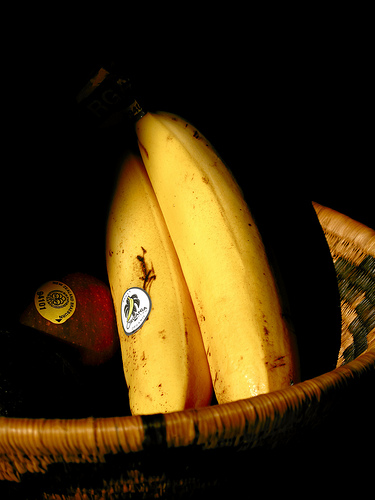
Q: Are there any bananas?
A: Yes, there is a banana.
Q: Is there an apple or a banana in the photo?
A: Yes, there is a banana.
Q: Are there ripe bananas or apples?
A: Yes, there is a ripe banana.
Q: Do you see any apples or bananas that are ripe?
A: Yes, the banana is ripe.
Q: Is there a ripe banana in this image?
A: Yes, there is a ripe banana.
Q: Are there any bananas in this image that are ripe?
A: Yes, there is a banana that is ripe.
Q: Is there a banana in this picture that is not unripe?
A: Yes, there is an ripe banana.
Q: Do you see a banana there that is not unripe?
A: Yes, there is an ripe banana.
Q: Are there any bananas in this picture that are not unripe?
A: Yes, there is an ripe banana.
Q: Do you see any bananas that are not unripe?
A: Yes, there is an ripe banana.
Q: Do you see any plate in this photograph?
A: No, there are no plates.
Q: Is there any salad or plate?
A: No, there are no plates or salad.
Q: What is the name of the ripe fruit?
A: The fruit is a banana.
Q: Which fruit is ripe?
A: The fruit is a banana.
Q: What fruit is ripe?
A: The fruit is a banana.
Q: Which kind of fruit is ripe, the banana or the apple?
A: The banana is ripe.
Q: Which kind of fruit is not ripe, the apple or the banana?
A: The apple is not ripe.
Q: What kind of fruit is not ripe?
A: The fruit is an apple.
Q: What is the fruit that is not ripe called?
A: The fruit is an apple.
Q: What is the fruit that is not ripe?
A: The fruit is an apple.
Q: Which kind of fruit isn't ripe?
A: The fruit is an apple.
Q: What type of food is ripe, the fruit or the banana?
A: The banana is ripe.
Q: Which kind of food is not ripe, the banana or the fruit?
A: The fruit is not ripe.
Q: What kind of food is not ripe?
A: The food is a fruit.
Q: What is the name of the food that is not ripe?
A: The food is a fruit.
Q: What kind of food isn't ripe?
A: The food is a fruit.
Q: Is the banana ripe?
A: Yes, the banana is ripe.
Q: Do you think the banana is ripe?
A: Yes, the banana is ripe.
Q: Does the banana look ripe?
A: Yes, the banana is ripe.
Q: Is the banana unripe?
A: No, the banana is ripe.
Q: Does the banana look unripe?
A: No, the banana is ripe.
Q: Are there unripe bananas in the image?
A: No, there is a banana but it is ripe.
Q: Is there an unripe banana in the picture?
A: No, there is a banana but it is ripe.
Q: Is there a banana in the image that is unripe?
A: No, there is a banana but it is ripe.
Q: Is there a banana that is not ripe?
A: No, there is a banana but it is ripe.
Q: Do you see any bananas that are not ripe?
A: No, there is a banana but it is ripe.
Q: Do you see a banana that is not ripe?
A: No, there is a banana but it is ripe.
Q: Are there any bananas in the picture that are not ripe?
A: No, there is a banana but it is ripe.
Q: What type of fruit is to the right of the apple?
A: The fruit is a banana.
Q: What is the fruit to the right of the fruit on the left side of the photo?
A: The fruit is a banana.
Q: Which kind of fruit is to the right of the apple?
A: The fruit is a banana.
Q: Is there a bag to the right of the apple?
A: No, there is a banana to the right of the apple.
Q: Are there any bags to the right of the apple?
A: No, there is a banana to the right of the apple.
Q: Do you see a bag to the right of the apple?
A: No, there is a banana to the right of the apple.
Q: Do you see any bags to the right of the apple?
A: No, there is a banana to the right of the apple.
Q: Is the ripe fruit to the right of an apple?
A: Yes, the banana is to the right of an apple.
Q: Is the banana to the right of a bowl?
A: No, the banana is to the right of an apple.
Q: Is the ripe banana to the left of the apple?
A: No, the banana is to the right of the apple.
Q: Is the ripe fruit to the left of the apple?
A: No, the banana is to the right of the apple.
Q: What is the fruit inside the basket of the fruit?
A: The fruit is a banana.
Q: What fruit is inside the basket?
A: The fruit is a banana.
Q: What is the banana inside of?
A: The banana is inside the basket.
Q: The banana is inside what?
A: The banana is inside the basket.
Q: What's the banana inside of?
A: The banana is inside the basket.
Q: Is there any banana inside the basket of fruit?
A: Yes, there is a banana inside the basket.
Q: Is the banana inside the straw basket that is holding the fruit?
A: Yes, the banana is inside the basket.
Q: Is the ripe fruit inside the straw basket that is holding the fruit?
A: Yes, the banana is inside the basket.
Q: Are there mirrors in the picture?
A: No, there are no mirrors.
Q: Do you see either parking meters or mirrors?
A: No, there are no mirrors or parking meters.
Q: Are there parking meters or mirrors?
A: No, there are no mirrors or parking meters.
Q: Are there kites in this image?
A: No, there are no kites.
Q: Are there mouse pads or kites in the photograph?
A: No, there are no kites or mouse pads.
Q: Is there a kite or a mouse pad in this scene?
A: No, there are no kites or mouse pads.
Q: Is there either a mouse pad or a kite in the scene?
A: No, there are no kites or mouse pads.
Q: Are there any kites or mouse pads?
A: No, there are no kites or mouse pads.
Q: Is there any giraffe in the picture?
A: No, there are no giraffes.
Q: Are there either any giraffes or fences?
A: No, there are no giraffes or fences.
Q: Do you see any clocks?
A: No, there are no clocks.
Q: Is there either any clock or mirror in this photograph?
A: No, there are no clocks or mirrors.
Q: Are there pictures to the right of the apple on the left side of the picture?
A: Yes, there is a picture to the right of the apple.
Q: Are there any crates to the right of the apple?
A: No, there is a picture to the right of the apple.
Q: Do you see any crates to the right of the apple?
A: No, there is a picture to the right of the apple.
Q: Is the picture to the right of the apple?
A: Yes, the picture is to the right of the apple.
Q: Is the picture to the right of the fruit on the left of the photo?
A: Yes, the picture is to the right of the apple.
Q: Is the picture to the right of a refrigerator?
A: No, the picture is to the right of the apple.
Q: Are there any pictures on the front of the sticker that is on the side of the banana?
A: Yes, there is a picture on the front of the sticker.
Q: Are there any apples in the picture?
A: Yes, there is an apple.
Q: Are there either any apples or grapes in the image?
A: Yes, there is an apple.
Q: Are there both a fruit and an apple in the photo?
A: Yes, there are both an apple and a fruit.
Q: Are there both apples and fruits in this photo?
A: Yes, there are both an apple and fruits.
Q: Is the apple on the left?
A: Yes, the apple is on the left of the image.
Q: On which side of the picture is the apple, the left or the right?
A: The apple is on the left of the image.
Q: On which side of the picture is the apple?
A: The apple is on the left of the image.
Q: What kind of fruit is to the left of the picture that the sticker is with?
A: The fruit is an apple.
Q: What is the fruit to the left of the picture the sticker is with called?
A: The fruit is an apple.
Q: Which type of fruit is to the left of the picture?
A: The fruit is an apple.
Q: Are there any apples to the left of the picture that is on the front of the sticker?
A: Yes, there is an apple to the left of the picture.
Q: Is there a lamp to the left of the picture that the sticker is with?
A: No, there is an apple to the left of the picture.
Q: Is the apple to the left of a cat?
A: No, the apple is to the left of the picture.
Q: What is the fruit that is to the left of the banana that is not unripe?
A: The fruit is an apple.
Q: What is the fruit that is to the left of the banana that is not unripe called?
A: The fruit is an apple.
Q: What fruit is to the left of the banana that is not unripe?
A: The fruit is an apple.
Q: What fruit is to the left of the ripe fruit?
A: The fruit is an apple.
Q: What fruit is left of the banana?
A: The fruit is an apple.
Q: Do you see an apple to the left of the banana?
A: Yes, there is an apple to the left of the banana.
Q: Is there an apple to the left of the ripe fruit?
A: Yes, there is an apple to the left of the banana.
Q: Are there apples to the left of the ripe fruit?
A: Yes, there is an apple to the left of the banana.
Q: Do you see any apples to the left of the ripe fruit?
A: Yes, there is an apple to the left of the banana.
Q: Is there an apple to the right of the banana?
A: No, the apple is to the left of the banana.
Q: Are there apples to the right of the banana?
A: No, the apple is to the left of the banana.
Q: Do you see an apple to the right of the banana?
A: No, the apple is to the left of the banana.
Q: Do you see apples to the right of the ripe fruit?
A: No, the apple is to the left of the banana.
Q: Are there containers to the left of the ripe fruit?
A: No, there is an apple to the left of the banana.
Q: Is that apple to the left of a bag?
A: No, the apple is to the left of the banana.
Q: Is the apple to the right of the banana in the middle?
A: No, the apple is to the left of the banana.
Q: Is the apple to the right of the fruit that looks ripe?
A: No, the apple is to the left of the banana.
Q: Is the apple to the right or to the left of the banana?
A: The apple is to the left of the banana.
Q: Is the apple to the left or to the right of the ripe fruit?
A: The apple is to the left of the banana.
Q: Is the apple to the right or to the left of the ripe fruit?
A: The apple is to the left of the banana.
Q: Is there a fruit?
A: Yes, there is a fruit.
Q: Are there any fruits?
A: Yes, there is a fruit.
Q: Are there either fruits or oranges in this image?
A: Yes, there is a fruit.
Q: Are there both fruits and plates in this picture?
A: No, there is a fruit but no plates.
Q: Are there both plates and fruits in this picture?
A: No, there is a fruit but no plates.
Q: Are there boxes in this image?
A: No, there are no boxes.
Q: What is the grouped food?
A: The food is a fruit.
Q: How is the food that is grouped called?
A: The food is a fruit.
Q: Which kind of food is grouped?
A: The food is a fruit.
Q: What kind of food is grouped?
A: The food is a fruit.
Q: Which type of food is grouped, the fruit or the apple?
A: The fruit is grouped.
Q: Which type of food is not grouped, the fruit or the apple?
A: The apple is not grouped.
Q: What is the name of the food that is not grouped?
A: The food is an apple.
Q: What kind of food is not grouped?
A: The food is an apple.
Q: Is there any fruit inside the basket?
A: Yes, there is a fruit inside the basket.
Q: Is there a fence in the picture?
A: No, there are no fences.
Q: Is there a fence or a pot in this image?
A: No, there are no fences or pots.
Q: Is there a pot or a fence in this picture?
A: No, there are no fences or pots.